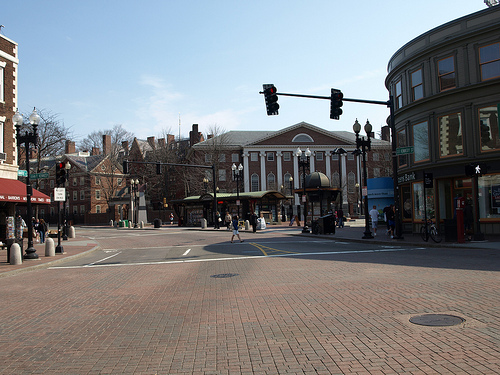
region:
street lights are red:
[264, 73, 409, 144]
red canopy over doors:
[6, 165, 86, 222]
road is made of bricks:
[67, 269, 392, 373]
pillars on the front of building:
[243, 143, 406, 233]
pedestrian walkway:
[76, 228, 405, 282]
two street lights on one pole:
[9, 99, 53, 148]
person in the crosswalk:
[217, 208, 279, 240]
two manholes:
[171, 245, 497, 372]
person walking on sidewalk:
[30, 212, 57, 252]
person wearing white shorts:
[230, 226, 241, 246]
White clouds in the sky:
[140, 67, 239, 124]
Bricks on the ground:
[178, 294, 303, 350]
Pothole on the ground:
[405, 303, 469, 335]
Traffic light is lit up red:
[49, 154, 72, 189]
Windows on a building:
[382, 56, 461, 108]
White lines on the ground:
[105, 244, 247, 272]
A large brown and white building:
[189, 119, 399, 231]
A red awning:
[1, 167, 54, 216]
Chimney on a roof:
[99, 127, 117, 158]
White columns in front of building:
[238, 143, 355, 216]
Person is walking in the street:
[223, 209, 250, 259]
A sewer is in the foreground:
[398, 302, 470, 344]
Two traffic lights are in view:
[253, 76, 351, 128]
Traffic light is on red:
[251, 73, 281, 125]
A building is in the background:
[194, 108, 397, 225]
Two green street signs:
[10, 162, 67, 191]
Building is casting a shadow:
[195, 216, 495, 281]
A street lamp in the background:
[350, 108, 384, 245]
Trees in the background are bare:
[88, 133, 220, 225]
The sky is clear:
[3, 3, 477, 134]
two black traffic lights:
[264, 55, 364, 140]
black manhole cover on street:
[382, 287, 479, 370]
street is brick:
[112, 277, 364, 365]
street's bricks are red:
[101, 286, 321, 369]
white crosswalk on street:
[102, 233, 448, 277]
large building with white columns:
[195, 111, 382, 208]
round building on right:
[368, 37, 498, 208]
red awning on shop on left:
[0, 165, 72, 208]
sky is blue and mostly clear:
[85, 27, 227, 114]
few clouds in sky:
[143, 56, 251, 140]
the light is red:
[226, 74, 334, 134]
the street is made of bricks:
[145, 264, 374, 371]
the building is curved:
[380, 25, 499, 233]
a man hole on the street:
[370, 287, 479, 341]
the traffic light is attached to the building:
[234, 81, 395, 133]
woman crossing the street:
[197, 199, 262, 250]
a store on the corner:
[2, 172, 80, 253]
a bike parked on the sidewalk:
[403, 196, 451, 248]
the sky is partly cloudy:
[57, 18, 243, 125]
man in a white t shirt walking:
[360, 193, 385, 232]